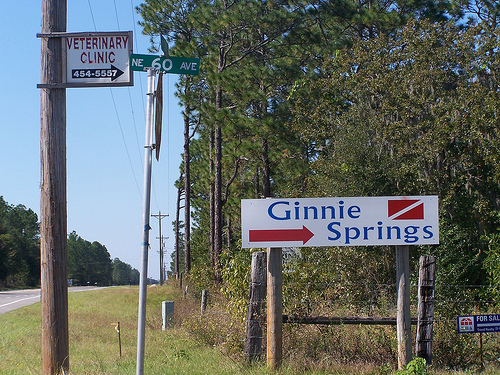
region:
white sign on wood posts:
[243, 194, 440, 248]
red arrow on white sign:
[245, 221, 312, 247]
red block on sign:
[386, 197, 426, 219]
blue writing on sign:
[262, 200, 362, 219]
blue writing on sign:
[325, 221, 433, 242]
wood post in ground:
[415, 250, 435, 364]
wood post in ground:
[238, 255, 268, 361]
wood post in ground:
[262, 248, 286, 363]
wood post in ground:
[395, 247, 412, 367]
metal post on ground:
[132, 68, 154, 373]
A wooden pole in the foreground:
[33, 1, 88, 373]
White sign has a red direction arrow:
[230, 187, 457, 261]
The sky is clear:
[1, 2, 214, 281]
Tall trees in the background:
[3, 185, 172, 295]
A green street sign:
[130, 46, 205, 80]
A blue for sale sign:
[451, 307, 498, 346]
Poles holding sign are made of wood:
[235, 191, 446, 371]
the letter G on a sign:
[266, 199, 292, 221]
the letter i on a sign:
[291, 196, 303, 221]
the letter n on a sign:
[301, 203, 317, 221]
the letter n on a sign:
[319, 202, 336, 219]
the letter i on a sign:
[333, 199, 349, 219]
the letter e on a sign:
[346, 203, 361, 218]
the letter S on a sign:
[325, 220, 342, 244]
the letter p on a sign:
[341, 223, 361, 246]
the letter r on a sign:
[361, 223, 376, 243]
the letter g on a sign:
[403, 220, 418, 245]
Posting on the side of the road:
[239, 195, 438, 368]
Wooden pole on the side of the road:
[34, 0, 133, 374]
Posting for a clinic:
[36, 28, 136, 90]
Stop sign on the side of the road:
[128, 34, 200, 374]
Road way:
[0, 283, 157, 321]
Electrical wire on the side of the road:
[151, 205, 171, 286]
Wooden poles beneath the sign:
[262, 246, 414, 372]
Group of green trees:
[1, 197, 157, 287]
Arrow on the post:
[249, 225, 313, 243]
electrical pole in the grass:
[151, 206, 173, 286]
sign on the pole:
[459, 315, 497, 331]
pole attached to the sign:
[474, 336, 489, 367]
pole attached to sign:
[260, 251, 288, 367]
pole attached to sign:
[392, 252, 409, 365]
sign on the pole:
[59, 30, 129, 86]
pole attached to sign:
[137, 71, 155, 373]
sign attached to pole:
[133, 52, 198, 74]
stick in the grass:
[112, 322, 127, 355]